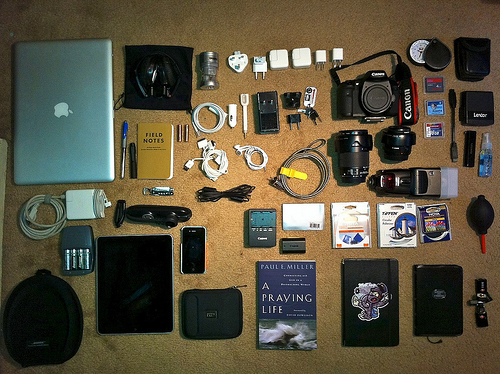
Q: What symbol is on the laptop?
A: Apple.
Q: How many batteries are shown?
A: Four.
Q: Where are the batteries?
A: In the charger.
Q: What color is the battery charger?
A: Gray.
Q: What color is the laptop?
A: Silver.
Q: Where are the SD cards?
A: Right, top.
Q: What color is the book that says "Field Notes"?
A: Tan.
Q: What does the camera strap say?
A: Canon.